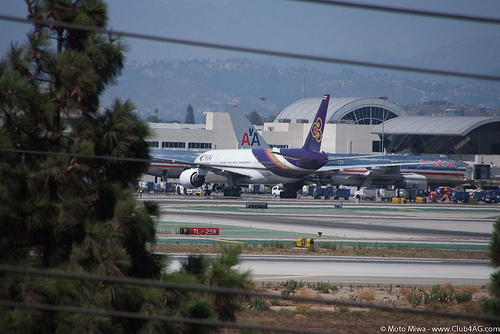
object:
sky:
[132, 11, 476, 79]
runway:
[206, 199, 466, 229]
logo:
[309, 111, 330, 147]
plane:
[185, 136, 326, 184]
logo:
[236, 118, 268, 148]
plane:
[244, 123, 468, 180]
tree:
[10, 3, 139, 288]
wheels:
[278, 184, 298, 204]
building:
[129, 98, 485, 166]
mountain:
[145, 57, 295, 100]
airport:
[147, 111, 472, 146]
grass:
[333, 239, 463, 267]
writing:
[380, 319, 477, 333]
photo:
[7, 5, 497, 248]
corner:
[365, 279, 498, 331]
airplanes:
[148, 141, 478, 196]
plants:
[409, 284, 477, 313]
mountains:
[139, 38, 474, 104]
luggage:
[309, 184, 369, 198]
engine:
[177, 163, 212, 192]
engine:
[384, 170, 431, 189]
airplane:
[325, 145, 481, 187]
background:
[20, 4, 496, 129]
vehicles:
[357, 186, 408, 199]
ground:
[186, 233, 483, 265]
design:
[304, 111, 326, 152]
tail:
[301, 93, 346, 153]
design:
[241, 123, 263, 145]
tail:
[224, 98, 275, 149]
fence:
[26, 260, 194, 328]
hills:
[114, 56, 478, 96]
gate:
[358, 138, 488, 169]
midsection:
[333, 150, 374, 172]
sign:
[183, 208, 225, 242]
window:
[302, 86, 399, 129]